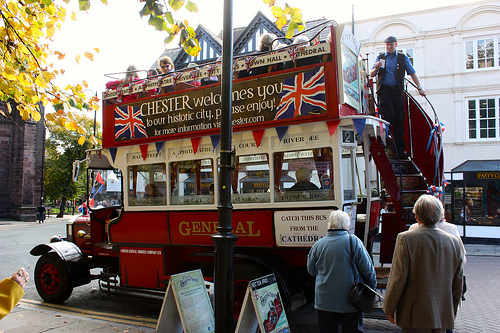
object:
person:
[381, 195, 468, 331]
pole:
[218, 0, 234, 331]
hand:
[12, 268, 31, 286]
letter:
[191, 222, 200, 233]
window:
[467, 100, 476, 111]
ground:
[475, 271, 500, 333]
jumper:
[307, 231, 377, 313]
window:
[272, 148, 333, 203]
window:
[235, 156, 269, 203]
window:
[170, 161, 196, 203]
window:
[151, 166, 167, 206]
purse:
[345, 233, 376, 313]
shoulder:
[343, 231, 362, 250]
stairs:
[383, 159, 410, 164]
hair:
[326, 209, 350, 231]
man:
[369, 35, 422, 157]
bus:
[25, 39, 442, 320]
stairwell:
[361, 67, 444, 321]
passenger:
[147, 69, 158, 81]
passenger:
[158, 57, 173, 74]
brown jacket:
[388, 225, 467, 329]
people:
[291, 36, 310, 47]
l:
[247, 220, 261, 237]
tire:
[33, 253, 76, 303]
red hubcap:
[38, 268, 60, 295]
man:
[288, 167, 320, 190]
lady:
[308, 210, 379, 330]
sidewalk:
[2, 322, 108, 332]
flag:
[276, 64, 327, 116]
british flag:
[273, 66, 327, 120]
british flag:
[114, 103, 148, 142]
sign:
[244, 273, 289, 331]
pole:
[219, 1, 235, 239]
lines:
[95, 311, 155, 321]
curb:
[21, 296, 164, 331]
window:
[463, 61, 475, 70]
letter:
[234, 220, 246, 234]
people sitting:
[96, 20, 367, 98]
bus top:
[107, 63, 320, 84]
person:
[120, 62, 147, 82]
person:
[259, 35, 274, 52]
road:
[2, 206, 484, 313]